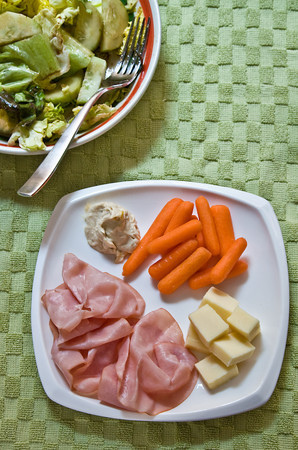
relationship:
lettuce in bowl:
[0, 0, 139, 150] [1, 0, 162, 158]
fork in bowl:
[16, 16, 152, 198] [1, 0, 162, 158]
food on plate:
[39, 196, 263, 420] [32, 178, 291, 423]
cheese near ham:
[183, 286, 262, 390] [41, 252, 198, 416]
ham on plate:
[41, 252, 198, 416] [32, 178, 291, 423]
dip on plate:
[82, 202, 141, 264] [32, 178, 291, 423]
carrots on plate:
[121, 195, 249, 297] [32, 178, 291, 423]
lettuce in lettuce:
[0, 0, 139, 150] [0, 0, 139, 150]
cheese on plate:
[183, 286, 262, 390] [32, 178, 291, 423]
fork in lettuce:
[16, 16, 152, 198] [0, 0, 139, 150]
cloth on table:
[0, 0, 297, 449] [3, 3, 296, 446]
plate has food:
[32, 178, 291, 423] [39, 196, 263, 420]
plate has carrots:
[32, 178, 291, 423] [121, 195, 249, 297]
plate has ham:
[32, 178, 291, 423] [41, 252, 198, 416]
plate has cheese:
[32, 178, 291, 423] [183, 286, 262, 390]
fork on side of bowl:
[16, 16, 152, 198] [1, 0, 162, 158]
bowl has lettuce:
[1, 0, 162, 158] [0, 0, 139, 150]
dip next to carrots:
[82, 202, 141, 264] [121, 195, 249, 297]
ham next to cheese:
[41, 252, 198, 416] [183, 286, 262, 390]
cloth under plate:
[0, 0, 297, 449] [32, 178, 291, 423]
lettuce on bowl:
[0, 0, 139, 150] [1, 0, 162, 158]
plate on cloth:
[32, 178, 291, 423] [0, 0, 297, 449]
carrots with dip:
[121, 195, 249, 297] [82, 202, 141, 264]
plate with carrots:
[32, 178, 291, 423] [121, 195, 249, 297]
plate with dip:
[32, 178, 291, 423] [82, 202, 141, 264]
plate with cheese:
[32, 178, 291, 423] [183, 286, 262, 390]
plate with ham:
[32, 178, 291, 423] [41, 252, 198, 416]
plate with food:
[32, 178, 291, 423] [39, 196, 263, 420]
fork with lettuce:
[16, 16, 152, 198] [0, 0, 139, 150]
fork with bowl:
[16, 16, 152, 198] [1, 0, 162, 158]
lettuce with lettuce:
[0, 0, 139, 150] [0, 0, 139, 150]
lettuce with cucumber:
[0, 0, 139, 150] [1, 0, 128, 105]